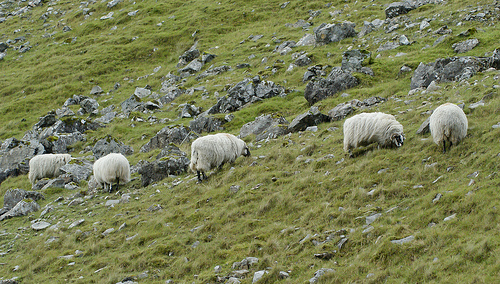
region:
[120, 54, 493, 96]
A whole bunch of rocks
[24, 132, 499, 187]
a whole bunch of sheep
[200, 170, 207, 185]
The sheep have black feet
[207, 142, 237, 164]
The sheep have white fur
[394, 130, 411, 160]
The sheep is eating grass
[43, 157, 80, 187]
The sheep is hiding behind a rock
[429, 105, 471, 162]
The rear of the sheep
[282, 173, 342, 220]
The grass is very green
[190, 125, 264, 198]
the sheep enjoy eating the grass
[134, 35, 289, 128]
many different sized rocks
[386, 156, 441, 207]
part of a grass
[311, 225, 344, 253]
part of some stones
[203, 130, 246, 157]
part of a stomach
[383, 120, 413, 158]
head of a sheep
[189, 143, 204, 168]
back of a sheep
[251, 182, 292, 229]
part of a ground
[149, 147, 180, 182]
part of a plant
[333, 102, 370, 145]
part of a sheep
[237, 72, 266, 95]
part of a rock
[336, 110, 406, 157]
white sheep grazing on grass covered hill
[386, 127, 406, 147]
black and white face of sheep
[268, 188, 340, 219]
patch of grass on hill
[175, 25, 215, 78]
grey rocks on grass covered hill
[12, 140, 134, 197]
two white sheep grazing on grass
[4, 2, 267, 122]
grass covered hill with grey rocks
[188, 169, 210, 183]
black sheep feet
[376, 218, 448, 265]
patch of green grass and grey rocks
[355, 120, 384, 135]
tan sheep fleece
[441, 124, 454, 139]
black sheep tail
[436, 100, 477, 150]
white sheep grazing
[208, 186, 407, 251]
green grass for grazing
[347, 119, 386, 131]
sheep's white wool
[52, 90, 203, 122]
rocks on grazing field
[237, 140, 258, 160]
head of sheep grazing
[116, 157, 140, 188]
tail of a white sheep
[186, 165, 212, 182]
hind legs of a white sheep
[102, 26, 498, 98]
scattered rocks on gracing field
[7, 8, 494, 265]
a green grazing field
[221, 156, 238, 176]
the front legs of a sheep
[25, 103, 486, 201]
a group of five sheep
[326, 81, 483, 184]
sheep wandering around the side of a mountain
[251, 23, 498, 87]
rocks mixed in with grassy patches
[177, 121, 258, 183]
white sheep with its face leaning down towards the grass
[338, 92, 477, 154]
two fluffy white sheep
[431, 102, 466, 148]
sheep behind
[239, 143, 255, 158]
black sheep face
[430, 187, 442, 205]
tiny bit of rock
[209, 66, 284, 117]
jutted out sharp gray rock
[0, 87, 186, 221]
rock formation